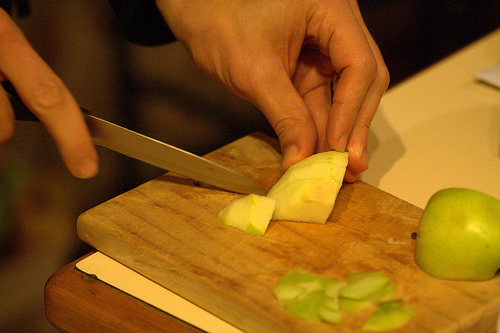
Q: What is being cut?
A: The apple.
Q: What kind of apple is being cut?
A: A green apple.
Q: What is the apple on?
A: A cutting board.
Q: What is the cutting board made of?
A: Wood.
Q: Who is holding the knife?
A: The man.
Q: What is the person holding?
A: A knife.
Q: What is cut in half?
A: The apple.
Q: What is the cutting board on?
A: The counter.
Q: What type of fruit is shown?
A: Apple.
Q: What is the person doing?
A: Cutting an apple.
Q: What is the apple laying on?
A: Cutting board.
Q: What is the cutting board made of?
A: Wood.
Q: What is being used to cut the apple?
A: A knife.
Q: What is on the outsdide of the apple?
A: Apple skin.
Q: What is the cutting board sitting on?
A: Table.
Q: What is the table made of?
A: Wood.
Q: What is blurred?
A: The background.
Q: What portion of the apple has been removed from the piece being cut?
A: Skin.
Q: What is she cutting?
A: Apples.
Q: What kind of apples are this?
A: Granny apples.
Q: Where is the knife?
A: On her right hand.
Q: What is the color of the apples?
A: Green.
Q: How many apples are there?
A: One.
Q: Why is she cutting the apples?
A: Easy to eat.